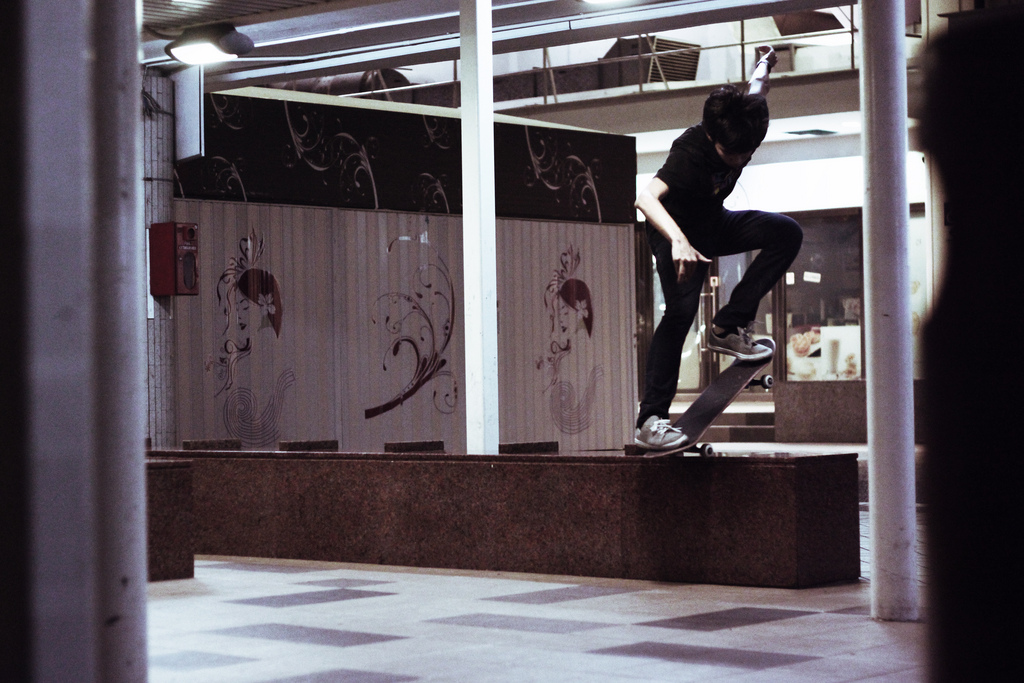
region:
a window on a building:
[768, 320, 873, 384]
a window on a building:
[735, 40, 854, 95]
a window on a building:
[530, 10, 749, 59]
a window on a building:
[521, 53, 755, 105]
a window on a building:
[225, 62, 457, 104]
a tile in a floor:
[222, 570, 371, 610]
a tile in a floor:
[188, 607, 378, 662]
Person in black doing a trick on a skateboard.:
[631, 42, 799, 447]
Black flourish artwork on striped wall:
[354, 231, 463, 418]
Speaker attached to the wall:
[151, 219, 203, 297]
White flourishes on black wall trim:
[180, 92, 636, 214]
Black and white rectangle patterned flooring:
[132, 544, 936, 678]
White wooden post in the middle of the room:
[464, 0, 500, 462]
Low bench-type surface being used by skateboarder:
[151, 446, 857, 584]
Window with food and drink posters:
[778, 216, 859, 381]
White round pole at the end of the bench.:
[862, 0, 917, 618]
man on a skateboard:
[589, 41, 855, 497]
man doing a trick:
[610, 39, 841, 486]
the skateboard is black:
[628, 310, 784, 466]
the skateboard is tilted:
[635, 314, 797, 467]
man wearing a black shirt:
[618, 92, 778, 249]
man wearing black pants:
[632, 205, 817, 420]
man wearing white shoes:
[631, 289, 786, 461]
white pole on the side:
[843, 0, 932, 629]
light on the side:
[163, 7, 269, 91]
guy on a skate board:
[626, 48, 800, 464]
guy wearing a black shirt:
[625, 50, 800, 465]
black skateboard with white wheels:
[632, 329, 784, 463]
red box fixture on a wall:
[148, 215, 207, 298]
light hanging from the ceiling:
[164, 25, 256, 71]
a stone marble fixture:
[147, 437, 863, 592]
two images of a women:
[205, 236, 613, 440]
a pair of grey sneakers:
[638, 315, 781, 451]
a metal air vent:
[492, 34, 696, 101]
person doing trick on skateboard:
[628, 38, 808, 463]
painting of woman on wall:
[200, 227, 301, 450]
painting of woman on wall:
[530, 235, 609, 439]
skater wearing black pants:
[633, 41, 805, 445]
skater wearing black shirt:
[625, 38, 808, 450]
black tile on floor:
[219, 586, 394, 612]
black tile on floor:
[423, 607, 622, 636]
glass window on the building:
[640, 43, 745, 85]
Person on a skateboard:
[534, 26, 845, 460]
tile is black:
[272, 607, 368, 672]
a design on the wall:
[227, 250, 289, 345]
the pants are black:
[645, 338, 677, 406]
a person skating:
[613, 66, 825, 411]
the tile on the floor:
[413, 575, 494, 662]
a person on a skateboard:
[599, 171, 862, 536]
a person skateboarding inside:
[593, 80, 762, 360]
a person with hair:
[582, 95, 737, 299]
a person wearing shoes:
[664, 262, 763, 458]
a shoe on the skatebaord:
[614, 414, 619, 437]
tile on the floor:
[669, 549, 824, 680]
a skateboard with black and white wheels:
[632, 328, 791, 468]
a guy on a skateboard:
[620, 47, 813, 455]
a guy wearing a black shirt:
[629, 57, 807, 468]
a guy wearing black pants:
[613, 45, 810, 469]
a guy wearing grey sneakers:
[618, 44, 799, 469]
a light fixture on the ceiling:
[166, 23, 255, 75]